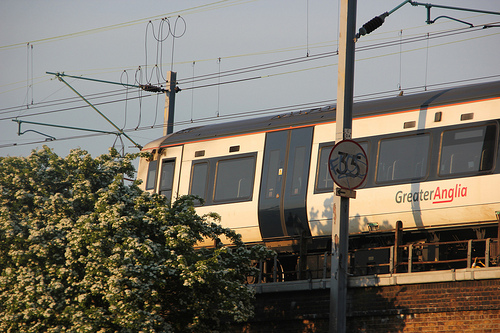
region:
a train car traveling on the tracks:
[129, 78, 499, 283]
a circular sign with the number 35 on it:
[327, 138, 371, 188]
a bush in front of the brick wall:
[0, 146, 261, 331]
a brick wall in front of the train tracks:
[225, 268, 499, 331]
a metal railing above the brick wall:
[235, 238, 499, 276]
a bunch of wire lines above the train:
[0, 0, 499, 147]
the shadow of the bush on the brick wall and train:
[241, 194, 408, 331]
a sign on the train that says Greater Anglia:
[391, 184, 471, 206]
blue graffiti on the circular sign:
[329, 150, 366, 186]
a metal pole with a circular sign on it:
[327, 0, 371, 332]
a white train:
[136, 85, 496, 272]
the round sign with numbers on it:
[325, 137, 366, 187]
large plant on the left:
[0, 142, 271, 327]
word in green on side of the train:
[392, 187, 432, 202]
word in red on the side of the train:
[431, 180, 466, 200]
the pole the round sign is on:
[327, 0, 353, 330]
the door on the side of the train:
[255, 121, 315, 236]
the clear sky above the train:
[0, 0, 496, 155]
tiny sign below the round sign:
[332, 185, 357, 196]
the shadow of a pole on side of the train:
[408, 183, 423, 226]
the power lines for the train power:
[1, 0, 194, 132]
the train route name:
[395, 180, 468, 204]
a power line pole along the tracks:
[328, 0, 363, 331]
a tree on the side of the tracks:
[0, 150, 266, 330]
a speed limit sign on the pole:
[328, 139, 368, 197]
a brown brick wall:
[348, 280, 498, 331]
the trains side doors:
[256, 125, 311, 240]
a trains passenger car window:
[375, 130, 435, 180]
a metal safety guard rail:
[346, 225, 496, 265]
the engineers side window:
[145, 155, 176, 199]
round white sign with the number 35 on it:
[305, 123, 376, 205]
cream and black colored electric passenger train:
[132, 72, 496, 271]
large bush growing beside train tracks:
[1, 138, 283, 331]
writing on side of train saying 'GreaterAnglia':
[385, 145, 490, 231]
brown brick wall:
[227, 263, 498, 330]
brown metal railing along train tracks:
[245, 220, 496, 330]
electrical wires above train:
[5, 0, 499, 154]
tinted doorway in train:
[242, 108, 331, 275]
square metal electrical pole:
[322, 0, 359, 330]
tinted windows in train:
[144, 115, 498, 247]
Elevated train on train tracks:
[136, 75, 498, 297]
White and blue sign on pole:
[323, 138, 370, 199]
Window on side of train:
[186, 149, 261, 208]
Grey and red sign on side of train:
[393, 182, 470, 205]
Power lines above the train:
[0, 1, 499, 148]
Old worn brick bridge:
[243, 278, 499, 332]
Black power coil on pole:
[353, 7, 386, 43]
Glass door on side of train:
[258, 124, 315, 241]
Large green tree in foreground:
[2, 141, 278, 331]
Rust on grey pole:
[331, 198, 347, 260]